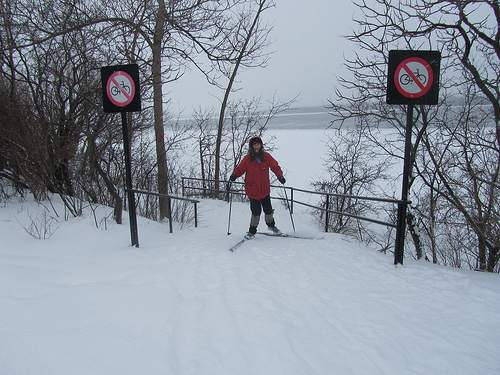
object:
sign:
[99, 62, 142, 113]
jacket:
[230, 151, 286, 201]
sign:
[385, 49, 442, 107]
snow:
[0, 128, 500, 375]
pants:
[249, 192, 276, 234]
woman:
[228, 135, 287, 241]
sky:
[0, 0, 500, 116]